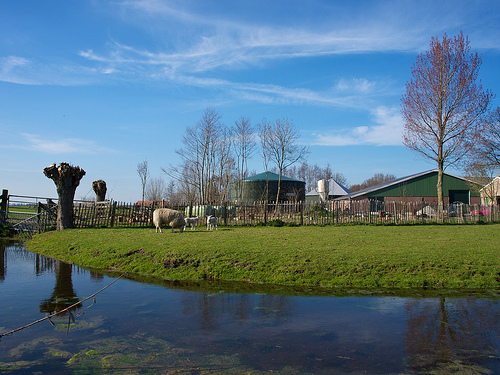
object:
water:
[1, 241, 500, 374]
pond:
[0, 241, 498, 374]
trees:
[133, 27, 499, 222]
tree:
[399, 29, 495, 222]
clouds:
[0, 2, 500, 207]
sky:
[0, 1, 499, 204]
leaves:
[399, 27, 496, 167]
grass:
[20, 223, 500, 297]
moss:
[2, 312, 500, 374]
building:
[328, 167, 498, 218]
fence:
[0, 188, 500, 234]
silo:
[229, 170, 307, 213]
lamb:
[183, 215, 202, 230]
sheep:
[153, 208, 186, 233]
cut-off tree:
[42, 162, 86, 230]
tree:
[92, 179, 107, 214]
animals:
[153, 208, 219, 234]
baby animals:
[184, 215, 219, 231]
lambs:
[183, 214, 218, 231]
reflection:
[40, 256, 83, 325]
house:
[328, 169, 485, 224]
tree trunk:
[42, 161, 88, 233]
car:
[470, 204, 499, 217]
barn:
[479, 176, 499, 220]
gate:
[4, 194, 116, 233]